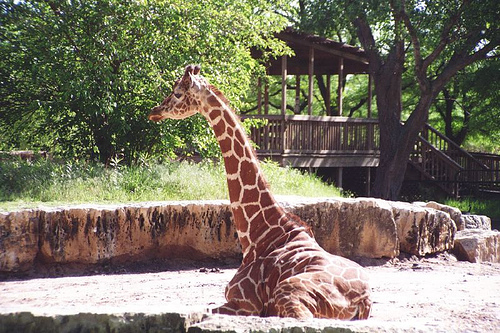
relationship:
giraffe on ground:
[137, 67, 388, 320] [134, 58, 387, 318]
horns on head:
[186, 58, 206, 74] [137, 55, 224, 126]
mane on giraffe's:
[210, 87, 320, 236] [134, 66, 375, 326]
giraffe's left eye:
[134, 66, 375, 326] [172, 90, 188, 101]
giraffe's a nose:
[134, 66, 375, 326] [145, 104, 155, 114]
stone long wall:
[6, 197, 498, 264] [4, 199, 498, 269]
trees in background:
[1, 3, 274, 154] [0, 2, 497, 201]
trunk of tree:
[370, 64, 426, 202] [304, 1, 492, 149]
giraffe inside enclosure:
[137, 67, 388, 320] [234, 28, 500, 207]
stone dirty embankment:
[6, 197, 498, 264] [5, 295, 499, 330]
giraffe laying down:
[137, 67, 388, 320] [193, 299, 376, 326]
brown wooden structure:
[247, 28, 499, 208] [249, 25, 499, 211]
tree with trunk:
[304, 1, 492, 149] [370, 64, 426, 202]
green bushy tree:
[4, 146, 343, 196] [304, 1, 492, 149]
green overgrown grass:
[4, 146, 343, 196] [12, 143, 349, 211]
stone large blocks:
[6, 197, 498, 264] [4, 204, 499, 275]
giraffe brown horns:
[137, 67, 388, 320] [186, 58, 206, 74]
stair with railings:
[411, 111, 497, 179] [404, 118, 464, 180]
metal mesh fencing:
[396, 175, 500, 196] [337, 174, 496, 211]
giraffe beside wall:
[137, 67, 388, 320] [4, 199, 498, 269]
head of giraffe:
[137, 55, 224, 126] [137, 67, 388, 320]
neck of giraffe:
[192, 101, 304, 244] [137, 67, 388, 320]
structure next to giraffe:
[249, 25, 500, 199] [137, 67, 388, 320]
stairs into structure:
[401, 114, 498, 194] [249, 25, 500, 199]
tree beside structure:
[304, 1, 492, 149] [249, 25, 500, 199]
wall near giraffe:
[4, 199, 498, 269] [137, 67, 388, 320]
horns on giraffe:
[186, 58, 206, 74] [137, 67, 388, 320]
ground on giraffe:
[134, 58, 387, 318] [137, 67, 388, 320]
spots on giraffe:
[204, 96, 231, 126] [137, 67, 388, 320]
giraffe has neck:
[137, 67, 388, 320] [192, 101, 304, 244]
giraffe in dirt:
[137, 67, 388, 320] [5, 254, 493, 330]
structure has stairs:
[249, 25, 500, 199] [401, 114, 498, 194]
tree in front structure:
[304, 1, 492, 149] [249, 25, 500, 199]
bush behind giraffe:
[439, 195, 499, 217] [137, 67, 388, 320]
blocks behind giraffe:
[456, 229, 499, 262] [137, 67, 388, 320]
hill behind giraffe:
[4, 151, 321, 197] [137, 67, 388, 320]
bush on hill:
[439, 195, 499, 217] [4, 151, 321, 197]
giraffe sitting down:
[137, 67, 388, 320] [193, 299, 376, 326]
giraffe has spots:
[137, 67, 388, 320] [204, 96, 231, 126]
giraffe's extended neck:
[134, 66, 375, 326] [192, 101, 304, 244]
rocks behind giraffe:
[382, 189, 499, 269] [137, 67, 388, 320]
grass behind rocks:
[12, 143, 349, 211] [382, 189, 499, 269]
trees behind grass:
[1, 3, 274, 154] [12, 143, 349, 211]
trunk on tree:
[370, 64, 426, 202] [304, 1, 492, 149]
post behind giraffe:
[274, 40, 293, 111] [137, 67, 388, 320]